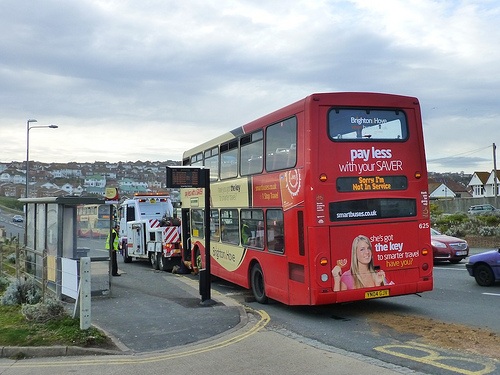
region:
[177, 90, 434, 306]
a double decker bus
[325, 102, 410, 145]
window on a bus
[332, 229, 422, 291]
advert on the back of a bus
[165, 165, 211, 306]
a black sign post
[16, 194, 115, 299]
a green bus stop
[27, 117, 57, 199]
a metal lamp post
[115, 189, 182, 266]
a white and red truck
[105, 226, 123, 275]
a man in safety attire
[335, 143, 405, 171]
whte lettering on red painted bus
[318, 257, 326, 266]
tail light on a bus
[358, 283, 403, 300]
yellow and black license plate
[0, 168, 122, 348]
bus stop on side of road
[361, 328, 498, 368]
yellow letter b on street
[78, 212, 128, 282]
man in yellow vest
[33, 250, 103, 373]
white and black sign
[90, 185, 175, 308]
tow truck on street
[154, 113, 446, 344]
large red and white bus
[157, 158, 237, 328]
black sign with orange letters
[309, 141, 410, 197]
white and orange letters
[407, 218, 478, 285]
red and silver car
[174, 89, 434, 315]
a red double decker bus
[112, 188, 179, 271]
a white and red tow truck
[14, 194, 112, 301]
an outdoor bus shelter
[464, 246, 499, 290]
a purple car in street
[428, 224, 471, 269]
a red car in street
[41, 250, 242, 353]
a paved city sidewalk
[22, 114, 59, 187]
an overhead light in distance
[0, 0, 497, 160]
a cloudy blue sky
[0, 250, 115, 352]
a patch of green grass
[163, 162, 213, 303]
an electronic street sign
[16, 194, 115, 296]
a glass bus stop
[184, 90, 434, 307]
a red double-decker bus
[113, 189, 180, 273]
a white tow truck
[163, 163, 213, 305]
sign at a bus stop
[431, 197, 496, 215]
a wooden privacy fence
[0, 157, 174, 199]
several homes in the distance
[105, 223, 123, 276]
a worker in a green vest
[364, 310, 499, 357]
brown material on the road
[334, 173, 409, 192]
a sign on the bus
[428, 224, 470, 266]
red car on the road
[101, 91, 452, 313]
a tow truck pulling a bus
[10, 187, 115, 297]
the shelter at a bus station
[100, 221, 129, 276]
a man wearing a yellow vest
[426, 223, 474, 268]
a red car driving down the street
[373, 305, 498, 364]
a pile of sand on the street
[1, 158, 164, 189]
several buildings in a residential area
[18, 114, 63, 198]
a metal lamppost in the distance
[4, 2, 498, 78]
an overcast sky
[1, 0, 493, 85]
a very cloudy sky